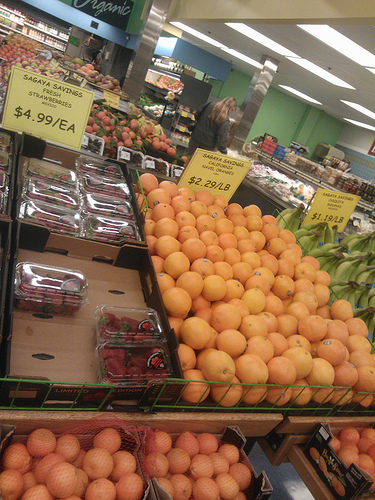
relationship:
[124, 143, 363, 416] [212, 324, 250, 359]
display has orange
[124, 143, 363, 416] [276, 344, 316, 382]
display has orange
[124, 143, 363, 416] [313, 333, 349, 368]
display has orange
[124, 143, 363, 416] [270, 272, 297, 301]
display has orange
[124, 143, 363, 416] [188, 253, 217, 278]
display has orange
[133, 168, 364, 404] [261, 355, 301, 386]
pile has orange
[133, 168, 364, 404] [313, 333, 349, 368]
pile has orange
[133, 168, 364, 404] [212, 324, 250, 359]
pile has orange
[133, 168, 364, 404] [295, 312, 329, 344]
pile has orange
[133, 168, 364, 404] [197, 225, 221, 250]
pile has orange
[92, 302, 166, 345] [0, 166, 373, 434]
strawberries on shelf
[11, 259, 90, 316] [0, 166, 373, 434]
strawberries on shelf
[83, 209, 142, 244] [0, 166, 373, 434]
strawberries on shelf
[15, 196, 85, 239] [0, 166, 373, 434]
strawberries on shelf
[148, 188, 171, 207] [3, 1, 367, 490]
orange in store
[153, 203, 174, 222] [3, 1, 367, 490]
orange in store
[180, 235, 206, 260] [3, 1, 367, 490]
orange in store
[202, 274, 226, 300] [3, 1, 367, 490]
orange in store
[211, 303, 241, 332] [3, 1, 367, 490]
orange in store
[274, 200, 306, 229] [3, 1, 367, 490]
banana in store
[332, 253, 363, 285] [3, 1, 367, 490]
banana in store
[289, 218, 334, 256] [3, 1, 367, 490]
banana in store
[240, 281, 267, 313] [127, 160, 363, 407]
orange inside box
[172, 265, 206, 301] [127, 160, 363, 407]
orange inside box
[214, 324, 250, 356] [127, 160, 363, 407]
orange inside box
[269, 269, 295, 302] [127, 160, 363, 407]
orange inside box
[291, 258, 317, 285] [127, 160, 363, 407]
orange inside box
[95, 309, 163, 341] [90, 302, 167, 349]
strawberries inside container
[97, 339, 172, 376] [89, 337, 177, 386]
strawberries inside container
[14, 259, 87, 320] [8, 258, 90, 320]
strawberries inside container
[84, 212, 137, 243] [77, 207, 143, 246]
strawberries inside container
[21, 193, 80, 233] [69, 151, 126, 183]
strawberries inside container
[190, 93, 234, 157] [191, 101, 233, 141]
lady has sweater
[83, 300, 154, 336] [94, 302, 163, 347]
strawberries in container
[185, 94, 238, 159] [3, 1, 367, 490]
lady in store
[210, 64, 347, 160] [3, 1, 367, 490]
wall in store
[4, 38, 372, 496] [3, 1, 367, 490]
produce in store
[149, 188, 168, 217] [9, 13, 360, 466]
oranges in store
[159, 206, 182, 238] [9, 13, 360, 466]
oranges in store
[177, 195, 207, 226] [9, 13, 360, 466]
oranges in store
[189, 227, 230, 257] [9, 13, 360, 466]
oranges in store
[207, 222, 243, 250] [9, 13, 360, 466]
oranges in store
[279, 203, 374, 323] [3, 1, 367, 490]
bananas in store